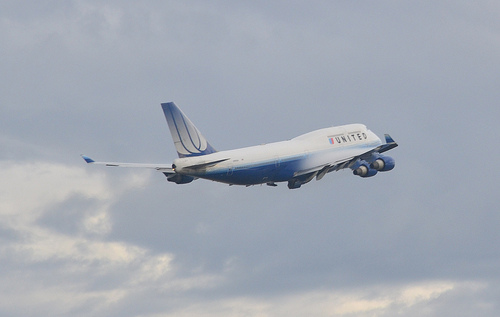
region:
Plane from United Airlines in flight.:
[79, 101, 398, 188]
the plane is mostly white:
[45, 52, 445, 251]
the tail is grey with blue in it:
[132, 93, 222, 153]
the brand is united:
[330, 111, 386, 156]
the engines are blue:
[338, 152, 408, 210]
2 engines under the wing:
[341, 150, 404, 193]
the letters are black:
[332, 120, 379, 148]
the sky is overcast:
[0, 21, 447, 305]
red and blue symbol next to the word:
[317, 114, 338, 164]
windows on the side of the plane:
[314, 126, 366, 143]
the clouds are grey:
[17, 173, 429, 304]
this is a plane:
[65, 88, 404, 219]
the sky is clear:
[104, 228, 201, 300]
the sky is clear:
[227, 217, 314, 289]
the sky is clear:
[399, 211, 469, 296]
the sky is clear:
[237, 60, 328, 151]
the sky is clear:
[47, 34, 105, 90]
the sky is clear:
[307, 20, 379, 75]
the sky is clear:
[421, 51, 484, 168]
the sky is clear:
[10, 91, 56, 160]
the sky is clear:
[262, 245, 325, 280]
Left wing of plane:
[75, 146, 181, 191]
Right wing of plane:
[285, 135, 395, 185]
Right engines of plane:
[350, 150, 400, 182]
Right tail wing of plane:
[185, 152, 240, 177]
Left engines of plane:
[160, 170, 190, 185]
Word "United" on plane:
[335, 125, 370, 145]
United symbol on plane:
[320, 130, 335, 147]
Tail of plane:
[152, 94, 219, 164]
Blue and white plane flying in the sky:
[65, 88, 415, 210]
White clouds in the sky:
[0, 146, 499, 316]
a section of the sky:
[196, 258, 297, 308]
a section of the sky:
[348, 215, 419, 281]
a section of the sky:
[30, 177, 116, 282]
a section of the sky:
[165, 20, 251, 77]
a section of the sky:
[350, 22, 460, 112]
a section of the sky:
[212, 35, 307, 108]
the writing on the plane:
[326, 120, 372, 150]